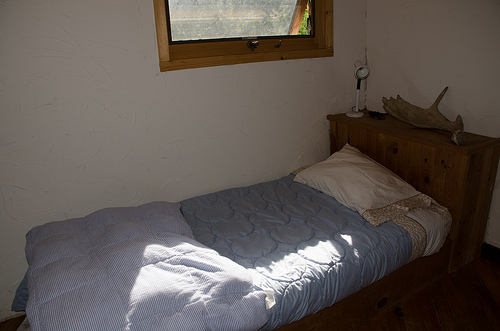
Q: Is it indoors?
A: Yes, it is indoors.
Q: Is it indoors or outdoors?
A: It is indoors.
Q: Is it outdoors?
A: No, it is indoors.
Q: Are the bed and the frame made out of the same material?
A: Yes, both the bed and the frame are made of wood.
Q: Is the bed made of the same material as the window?
A: Yes, both the bed and the window are made of wood.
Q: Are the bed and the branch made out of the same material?
A: Yes, both the bed and the branch are made of wood.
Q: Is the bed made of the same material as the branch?
A: Yes, both the bed and the branch are made of wood.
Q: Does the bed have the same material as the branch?
A: Yes, both the bed and the branch are made of wood.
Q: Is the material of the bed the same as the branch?
A: Yes, both the bed and the branch are made of wood.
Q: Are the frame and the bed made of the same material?
A: Yes, both the frame and the bed are made of wood.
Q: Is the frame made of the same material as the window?
A: Yes, both the frame and the window are made of wood.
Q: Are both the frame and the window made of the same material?
A: Yes, both the frame and the window are made of wood.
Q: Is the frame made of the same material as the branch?
A: Yes, both the frame and the branch are made of wood.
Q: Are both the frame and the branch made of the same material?
A: Yes, both the frame and the branch are made of wood.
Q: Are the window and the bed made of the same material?
A: Yes, both the window and the bed are made of wood.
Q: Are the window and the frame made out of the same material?
A: Yes, both the window and the frame are made of wood.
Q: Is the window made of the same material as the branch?
A: Yes, both the window and the branch are made of wood.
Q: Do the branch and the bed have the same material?
A: Yes, both the branch and the bed are made of wood.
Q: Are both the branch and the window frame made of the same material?
A: Yes, both the branch and the frame are made of wood.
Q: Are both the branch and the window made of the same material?
A: Yes, both the branch and the window are made of wood.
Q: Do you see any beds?
A: Yes, there is a bed.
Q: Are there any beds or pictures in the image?
A: Yes, there is a bed.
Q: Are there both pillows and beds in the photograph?
A: Yes, there are both a bed and pillows.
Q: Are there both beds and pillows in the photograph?
A: Yes, there are both a bed and pillows.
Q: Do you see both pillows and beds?
A: Yes, there are both a bed and pillows.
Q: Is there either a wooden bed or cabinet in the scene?
A: Yes, there is a wood bed.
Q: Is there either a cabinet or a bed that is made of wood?
A: Yes, the bed is made of wood.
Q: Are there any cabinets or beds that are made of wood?
A: Yes, the bed is made of wood.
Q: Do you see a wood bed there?
A: Yes, there is a wood bed.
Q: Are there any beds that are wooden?
A: Yes, there is a bed that is wooden.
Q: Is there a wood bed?
A: Yes, there is a bed that is made of wood.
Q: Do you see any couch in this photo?
A: No, there are no couches.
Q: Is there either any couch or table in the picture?
A: No, there are no couches or tables.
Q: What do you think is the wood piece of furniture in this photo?
A: The piece of furniture is a bed.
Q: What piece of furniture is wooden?
A: The piece of furniture is a bed.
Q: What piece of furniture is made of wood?
A: The piece of furniture is a bed.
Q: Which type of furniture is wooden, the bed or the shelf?
A: The bed is wooden.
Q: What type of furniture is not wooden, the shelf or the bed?
A: The shelf is not wooden.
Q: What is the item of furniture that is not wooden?
A: The piece of furniture is a shelf.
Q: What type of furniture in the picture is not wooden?
A: The furniture is a shelf.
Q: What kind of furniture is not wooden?
A: The furniture is a shelf.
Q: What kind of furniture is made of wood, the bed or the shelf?
A: The bed is made of wood.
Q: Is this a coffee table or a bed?
A: This is a bed.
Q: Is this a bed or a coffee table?
A: This is a bed.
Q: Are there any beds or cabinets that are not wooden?
A: No, there is a bed but it is wooden.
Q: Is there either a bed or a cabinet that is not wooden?
A: No, there is a bed but it is wooden.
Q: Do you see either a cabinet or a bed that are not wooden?
A: No, there is a bed but it is wooden.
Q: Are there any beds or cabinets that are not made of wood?
A: No, there is a bed but it is made of wood.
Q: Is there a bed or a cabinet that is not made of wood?
A: No, there is a bed but it is made of wood.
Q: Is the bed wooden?
A: Yes, the bed is wooden.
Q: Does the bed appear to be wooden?
A: Yes, the bed is wooden.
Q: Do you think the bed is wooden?
A: Yes, the bed is wooden.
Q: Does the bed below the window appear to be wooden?
A: Yes, the bed is wooden.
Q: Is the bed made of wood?
A: Yes, the bed is made of wood.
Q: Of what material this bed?
A: The bed is made of wood.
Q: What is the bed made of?
A: The bed is made of wood.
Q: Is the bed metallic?
A: No, the bed is wooden.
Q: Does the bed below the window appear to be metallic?
A: No, the bed is wooden.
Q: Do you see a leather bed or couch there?
A: No, there is a bed but it is wooden.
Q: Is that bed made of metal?
A: No, the bed is made of wood.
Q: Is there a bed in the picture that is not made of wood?
A: No, there is a bed but it is made of wood.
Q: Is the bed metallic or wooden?
A: The bed is wooden.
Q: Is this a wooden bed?
A: Yes, this is a wooden bed.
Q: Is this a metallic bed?
A: No, this is a wooden bed.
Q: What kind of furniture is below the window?
A: The piece of furniture is a bed.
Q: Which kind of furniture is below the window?
A: The piece of furniture is a bed.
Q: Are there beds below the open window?
A: Yes, there is a bed below the window.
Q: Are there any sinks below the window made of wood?
A: No, there is a bed below the window.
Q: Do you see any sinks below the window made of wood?
A: No, there is a bed below the window.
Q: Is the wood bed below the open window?
A: Yes, the bed is below the window.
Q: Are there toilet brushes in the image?
A: No, there are no toilet brushes.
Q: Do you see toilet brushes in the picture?
A: No, there are no toilet brushes.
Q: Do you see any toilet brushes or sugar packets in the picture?
A: No, there are no toilet brushes or sugar packets.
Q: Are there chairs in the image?
A: No, there are no chairs.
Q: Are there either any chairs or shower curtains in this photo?
A: No, there are no chairs or shower curtains.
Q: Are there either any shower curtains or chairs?
A: No, there are no chairs or shower curtains.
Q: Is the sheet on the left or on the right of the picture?
A: The sheet is on the right of the image.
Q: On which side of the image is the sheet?
A: The sheet is on the right of the image.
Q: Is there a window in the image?
A: Yes, there is a window.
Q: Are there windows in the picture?
A: Yes, there is a window.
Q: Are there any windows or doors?
A: Yes, there is a window.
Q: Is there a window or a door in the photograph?
A: Yes, there is a window.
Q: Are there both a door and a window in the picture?
A: No, there is a window but no doors.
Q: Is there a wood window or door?
A: Yes, there is a wood window.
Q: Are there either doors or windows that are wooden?
A: Yes, the window is wooden.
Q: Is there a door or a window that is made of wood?
A: Yes, the window is made of wood.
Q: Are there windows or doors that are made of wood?
A: Yes, the window is made of wood.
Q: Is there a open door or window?
A: Yes, there is an open window.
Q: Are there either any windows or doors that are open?
A: Yes, the window is open.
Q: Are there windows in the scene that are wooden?
A: Yes, there is a wood window.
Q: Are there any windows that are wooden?
A: Yes, there is a window that is wooden.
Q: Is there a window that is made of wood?
A: Yes, there is a window that is made of wood.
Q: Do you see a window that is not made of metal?
A: Yes, there is a window that is made of wood.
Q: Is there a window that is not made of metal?
A: Yes, there is a window that is made of wood.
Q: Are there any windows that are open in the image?
A: Yes, there is an open window.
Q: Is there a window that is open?
A: Yes, there is a window that is open.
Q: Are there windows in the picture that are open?
A: Yes, there is a window that is open.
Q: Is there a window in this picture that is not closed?
A: Yes, there is a open window.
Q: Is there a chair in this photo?
A: No, there are no chairs.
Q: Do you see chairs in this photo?
A: No, there are no chairs.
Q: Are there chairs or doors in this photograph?
A: No, there are no chairs or doors.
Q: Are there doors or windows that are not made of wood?
A: No, there is a window but it is made of wood.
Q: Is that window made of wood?
A: Yes, the window is made of wood.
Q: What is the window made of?
A: The window is made of wood.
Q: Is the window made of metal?
A: No, the window is made of wood.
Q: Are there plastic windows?
A: No, there is a window but it is made of wood.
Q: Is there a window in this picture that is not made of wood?
A: No, there is a window but it is made of wood.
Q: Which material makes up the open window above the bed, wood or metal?
A: The window is made of wood.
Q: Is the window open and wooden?
A: Yes, the window is open and wooden.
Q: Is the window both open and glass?
A: No, the window is open but wooden.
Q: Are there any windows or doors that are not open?
A: No, there is a window but it is open.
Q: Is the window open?
A: Yes, the window is open.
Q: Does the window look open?
A: Yes, the window is open.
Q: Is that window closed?
A: No, the window is open.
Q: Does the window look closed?
A: No, the window is open.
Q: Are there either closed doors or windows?
A: No, there is a window but it is open.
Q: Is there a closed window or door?
A: No, there is a window but it is open.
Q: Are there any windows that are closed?
A: No, there is a window but it is open.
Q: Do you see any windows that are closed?
A: No, there is a window but it is open.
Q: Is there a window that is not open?
A: No, there is a window but it is open.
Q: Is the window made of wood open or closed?
A: The window is open.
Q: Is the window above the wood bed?
A: Yes, the window is above the bed.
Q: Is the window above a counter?
A: No, the window is above the bed.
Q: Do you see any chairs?
A: No, there are no chairs.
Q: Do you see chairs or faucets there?
A: No, there are no chairs or faucets.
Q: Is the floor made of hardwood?
A: Yes, the floor is made of hardwood.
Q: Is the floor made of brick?
A: No, the floor is made of hardwood.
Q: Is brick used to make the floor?
A: No, the floor is made of hardwood.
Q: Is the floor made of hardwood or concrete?
A: The floor is made of hardwood.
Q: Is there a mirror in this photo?
A: No, there are no mirrors.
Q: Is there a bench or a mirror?
A: No, there are no mirrors or benches.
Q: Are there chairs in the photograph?
A: No, there are no chairs.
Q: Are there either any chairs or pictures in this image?
A: No, there are no chairs or pictures.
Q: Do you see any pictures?
A: No, there are no pictures.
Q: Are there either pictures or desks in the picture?
A: No, there are no pictures or desks.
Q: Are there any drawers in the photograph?
A: No, there are no drawers.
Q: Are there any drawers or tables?
A: No, there are no drawers or tables.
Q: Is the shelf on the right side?
A: Yes, the shelf is on the right of the image.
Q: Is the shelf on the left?
A: No, the shelf is on the right of the image.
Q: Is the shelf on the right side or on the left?
A: The shelf is on the right of the image.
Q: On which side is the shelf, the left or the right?
A: The shelf is on the right of the image.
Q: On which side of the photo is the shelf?
A: The shelf is on the right of the image.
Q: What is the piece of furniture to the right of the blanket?
A: The piece of furniture is a shelf.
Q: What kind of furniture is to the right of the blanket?
A: The piece of furniture is a shelf.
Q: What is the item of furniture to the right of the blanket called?
A: The piece of furniture is a shelf.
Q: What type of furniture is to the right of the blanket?
A: The piece of furniture is a shelf.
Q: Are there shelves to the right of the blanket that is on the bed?
A: Yes, there is a shelf to the right of the blanket.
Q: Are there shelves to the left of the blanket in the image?
A: No, the shelf is to the right of the blanket.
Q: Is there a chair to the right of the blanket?
A: No, there is a shelf to the right of the blanket.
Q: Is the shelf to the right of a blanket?
A: Yes, the shelf is to the right of a blanket.